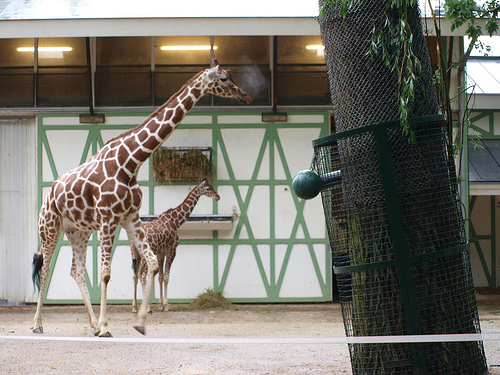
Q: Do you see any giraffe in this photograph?
A: Yes, there is a giraffe.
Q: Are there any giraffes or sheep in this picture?
A: Yes, there is a giraffe.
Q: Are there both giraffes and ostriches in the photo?
A: No, there is a giraffe but no ostriches.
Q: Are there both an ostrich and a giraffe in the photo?
A: No, there is a giraffe but no ostriches.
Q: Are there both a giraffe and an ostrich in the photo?
A: No, there is a giraffe but no ostriches.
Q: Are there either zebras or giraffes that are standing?
A: Yes, the giraffe is standing.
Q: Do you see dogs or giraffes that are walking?
A: Yes, the giraffe is walking.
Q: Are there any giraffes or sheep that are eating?
A: Yes, the giraffe is eating.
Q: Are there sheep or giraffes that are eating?
A: Yes, the giraffe is eating.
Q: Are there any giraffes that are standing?
A: Yes, there is a giraffe that is standing.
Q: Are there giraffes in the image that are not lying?
A: Yes, there is a giraffe that is standing.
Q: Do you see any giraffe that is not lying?
A: Yes, there is a giraffe that is standing .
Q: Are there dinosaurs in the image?
A: No, there are no dinosaurs.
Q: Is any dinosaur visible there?
A: No, there are no dinosaurs.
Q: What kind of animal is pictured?
A: The animal is a giraffe.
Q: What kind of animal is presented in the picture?
A: The animal is a giraffe.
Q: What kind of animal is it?
A: The animal is a giraffe.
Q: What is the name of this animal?
A: This is a giraffe.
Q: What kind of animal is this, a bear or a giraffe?
A: This is a giraffe.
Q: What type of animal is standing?
A: The animal is a giraffe.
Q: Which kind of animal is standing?
A: The animal is a giraffe.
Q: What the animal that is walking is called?
A: The animal is a giraffe.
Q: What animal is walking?
A: The animal is a giraffe.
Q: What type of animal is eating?
A: The animal is a giraffe.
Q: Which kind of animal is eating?
A: The animal is a giraffe.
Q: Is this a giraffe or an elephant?
A: This is a giraffe.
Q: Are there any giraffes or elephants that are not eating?
A: No, there is a giraffe but it is eating.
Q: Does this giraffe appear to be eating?
A: Yes, the giraffe is eating.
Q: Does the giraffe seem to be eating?
A: Yes, the giraffe is eating.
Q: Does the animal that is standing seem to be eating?
A: Yes, the giraffe is eating.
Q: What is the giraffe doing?
A: The giraffe is eating.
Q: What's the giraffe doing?
A: The giraffe is eating.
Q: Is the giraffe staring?
A: No, the giraffe is eating.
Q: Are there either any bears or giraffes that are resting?
A: No, there is a giraffe but it is eating.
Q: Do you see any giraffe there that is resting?
A: No, there is a giraffe but it is eating.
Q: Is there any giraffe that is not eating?
A: No, there is a giraffe but it is eating.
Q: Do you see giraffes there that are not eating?
A: No, there is a giraffe but it is eating.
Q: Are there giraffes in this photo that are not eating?
A: No, there is a giraffe but it is eating.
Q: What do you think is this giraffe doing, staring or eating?
A: The giraffe is eating.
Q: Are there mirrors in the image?
A: No, there are no mirrors.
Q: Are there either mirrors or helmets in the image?
A: No, there are no mirrors or helmets.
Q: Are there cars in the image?
A: No, there are no cars.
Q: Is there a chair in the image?
A: No, there are no chairs.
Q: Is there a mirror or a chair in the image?
A: No, there are no chairs or mirrors.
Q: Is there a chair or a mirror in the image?
A: No, there are no chairs or mirrors.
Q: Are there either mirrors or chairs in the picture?
A: No, there are no chairs or mirrors.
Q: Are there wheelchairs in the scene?
A: No, there are no wheelchairs.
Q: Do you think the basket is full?
A: Yes, the basket is full.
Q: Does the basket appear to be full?
A: Yes, the basket is full.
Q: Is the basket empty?
A: No, the basket is full.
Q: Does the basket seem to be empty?
A: No, the basket is full.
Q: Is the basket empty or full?
A: The basket is full.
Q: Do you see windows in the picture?
A: Yes, there are windows.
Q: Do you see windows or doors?
A: Yes, there are windows.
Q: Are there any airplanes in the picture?
A: No, there are no airplanes.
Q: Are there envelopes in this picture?
A: No, there are no envelopes.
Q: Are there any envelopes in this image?
A: No, there are no envelopes.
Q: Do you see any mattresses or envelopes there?
A: No, there are no envelopes or mattresses.